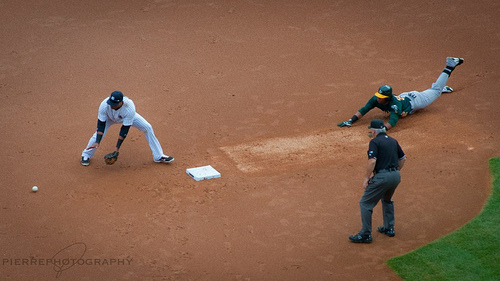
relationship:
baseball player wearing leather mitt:
[68, 75, 169, 192] [102, 143, 126, 167]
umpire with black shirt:
[348, 116, 403, 242] [367, 132, 406, 172]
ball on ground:
[28, 180, 42, 196] [24, 212, 97, 234]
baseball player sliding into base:
[337, 56, 465, 138] [187, 166, 223, 183]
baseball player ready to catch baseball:
[80, 90, 175, 166] [20, 176, 47, 196]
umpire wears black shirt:
[348, 119, 406, 243] [365, 134, 405, 171]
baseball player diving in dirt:
[338, 51, 467, 139] [1, 0, 498, 277]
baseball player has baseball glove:
[80, 90, 175, 166] [103, 151, 119, 166]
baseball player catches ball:
[80, 90, 175, 166] [31, 185, 37, 192]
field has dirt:
[0, 1, 498, 278] [1, 0, 498, 277]